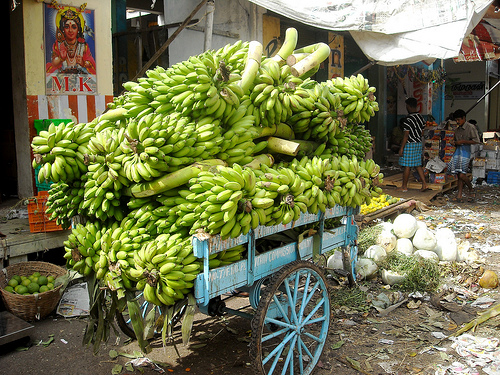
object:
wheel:
[248, 260, 332, 375]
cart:
[113, 200, 360, 375]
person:
[395, 96, 430, 192]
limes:
[3, 271, 58, 295]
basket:
[0, 260, 69, 323]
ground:
[0, 190, 500, 375]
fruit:
[33, 25, 368, 296]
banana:
[51, 146, 67, 154]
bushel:
[32, 121, 93, 182]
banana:
[221, 201, 236, 212]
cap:
[405, 97, 418, 106]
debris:
[435, 268, 496, 330]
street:
[100, 183, 498, 373]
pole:
[202, 0, 214, 52]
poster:
[42, 1, 97, 95]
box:
[482, 131, 499, 143]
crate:
[429, 173, 447, 184]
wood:
[361, 197, 417, 223]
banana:
[258, 74, 275, 85]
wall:
[28, 94, 115, 196]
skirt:
[398, 141, 423, 166]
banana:
[159, 262, 175, 276]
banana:
[195, 74, 212, 83]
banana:
[356, 74, 364, 89]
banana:
[146, 78, 157, 83]